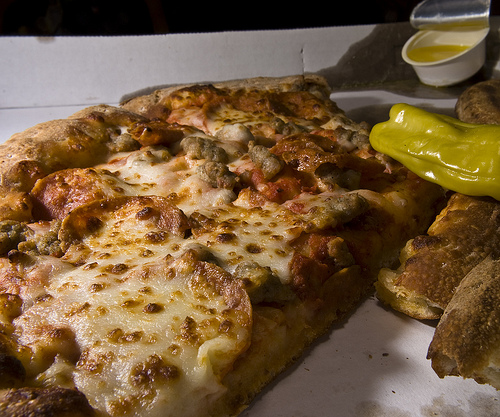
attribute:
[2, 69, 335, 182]
crust — brown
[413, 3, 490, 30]
lid — tinfoil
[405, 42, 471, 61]
dipping sauce — yellow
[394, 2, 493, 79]
sauce — cheesy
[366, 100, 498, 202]
jpepper — yellow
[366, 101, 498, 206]
peppercini — green 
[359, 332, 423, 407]
cardboard — white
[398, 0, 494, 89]
container — shiny